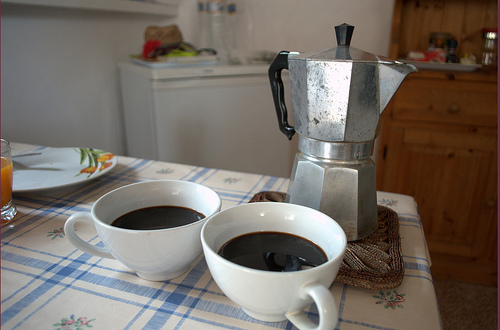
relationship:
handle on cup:
[291, 285, 330, 329] [187, 175, 359, 324]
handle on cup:
[63, 210, 113, 260] [72, 175, 228, 294]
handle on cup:
[283, 283, 339, 329] [200, 200, 348, 328]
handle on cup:
[63, 210, 113, 260] [65, 178, 220, 280]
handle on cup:
[63, 210, 113, 260] [43, 161, 220, 291]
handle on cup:
[283, 283, 339, 329] [197, 202, 374, 328]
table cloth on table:
[1, 154, 444, 329] [0, 137, 437, 329]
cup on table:
[218, 187, 328, 314] [9, 231, 192, 324]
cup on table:
[84, 169, 214, 290] [9, 231, 192, 324]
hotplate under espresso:
[352, 242, 413, 289] [263, 23, 415, 236]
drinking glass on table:
[0, 140, 19, 228] [0, 137, 437, 329]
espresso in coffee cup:
[217, 230, 329, 275] [202, 186, 342, 326]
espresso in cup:
[231, 230, 295, 261] [199, 201, 348, 330]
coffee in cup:
[114, 203, 201, 226] [65, 171, 220, 286]